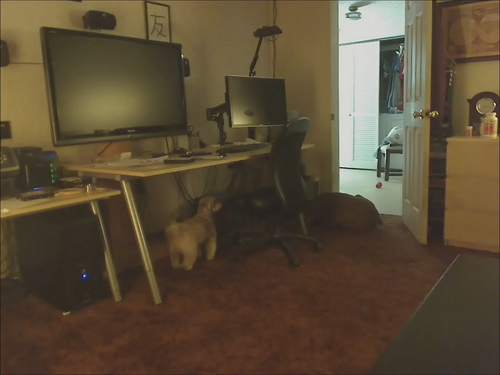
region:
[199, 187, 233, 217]
the head of a dog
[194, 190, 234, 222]
the face of a dog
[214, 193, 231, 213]
the nose of a dog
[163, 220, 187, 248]
the tail of a dog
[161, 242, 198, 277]
the legs of a dog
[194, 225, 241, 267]
the front legs of a dog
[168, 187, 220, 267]
the body of a dog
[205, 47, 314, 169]
a computer on a desk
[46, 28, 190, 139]
large flat screen TV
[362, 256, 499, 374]
throw rug on the floor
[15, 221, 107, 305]
a PC tower has a blue light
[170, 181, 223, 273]
little dog stands under a table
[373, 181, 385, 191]
a red toy ball in the next room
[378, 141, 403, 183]
legs of a black chair on a white floor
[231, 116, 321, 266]
a rolling black office chair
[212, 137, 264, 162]
a black keyboard on the table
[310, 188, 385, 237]
dog sleeps in the doorway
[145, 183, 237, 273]
animal in the room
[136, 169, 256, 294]
animal under a table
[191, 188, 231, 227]
head of the animal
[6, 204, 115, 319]
computer under the table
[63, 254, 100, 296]
blue light on the computer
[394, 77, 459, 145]
door handle in the photo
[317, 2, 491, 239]
door in the photo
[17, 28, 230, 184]
television in room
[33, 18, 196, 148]
a large black t.v.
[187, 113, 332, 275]
a black desk chair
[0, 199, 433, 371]
a pink section of carpet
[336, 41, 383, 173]
part of a white door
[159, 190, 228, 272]
a small brown dog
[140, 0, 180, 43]
a black picture frame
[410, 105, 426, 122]
a doorknob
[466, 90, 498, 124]
a wooden clock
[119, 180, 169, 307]
a long gray table leg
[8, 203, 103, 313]
a large black cpu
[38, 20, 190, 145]
a large screen turned off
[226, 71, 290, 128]
the black roman numeral XII on the clock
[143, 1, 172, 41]
a symbol framed on the wall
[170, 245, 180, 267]
the white leg of a dog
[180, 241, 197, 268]
the white leg of a dog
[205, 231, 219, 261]
the white leg of a dog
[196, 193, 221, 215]
the head of a dog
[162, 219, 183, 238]
the tail of a dog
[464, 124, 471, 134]
a white bottle on the dresser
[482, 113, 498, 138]
a white bottle on the dresser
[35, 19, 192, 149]
Large computer screen above a wooden table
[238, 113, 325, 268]
Computer chair positioned underneath a table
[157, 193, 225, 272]
Small white dog underneath a table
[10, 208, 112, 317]
CPU underneath a table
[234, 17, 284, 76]
Black lamp above a computer screen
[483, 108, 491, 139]
nick knack on the counter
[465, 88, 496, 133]
nick knack on the counter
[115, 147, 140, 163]
nick knack on the counter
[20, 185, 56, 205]
nick knack on the counter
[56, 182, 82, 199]
nick knack on the counter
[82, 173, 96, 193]
nick knack on the counter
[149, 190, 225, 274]
white dog under the table